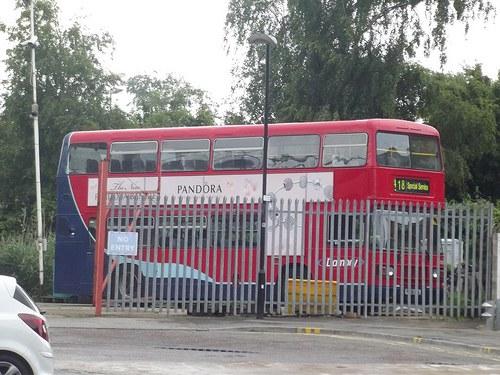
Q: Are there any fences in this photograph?
A: Yes, there is a fence.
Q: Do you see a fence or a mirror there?
A: Yes, there is a fence.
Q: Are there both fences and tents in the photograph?
A: No, there is a fence but no tents.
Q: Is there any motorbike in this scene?
A: No, there are no motorcycles.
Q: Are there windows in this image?
A: Yes, there is a window.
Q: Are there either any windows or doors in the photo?
A: Yes, there is a window.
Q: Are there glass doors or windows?
A: Yes, there is a glass window.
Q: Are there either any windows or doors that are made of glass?
A: Yes, the window is made of glass.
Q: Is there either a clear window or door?
A: Yes, there is a clear window.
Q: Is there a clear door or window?
A: Yes, there is a clear window.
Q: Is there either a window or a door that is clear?
A: Yes, the window is clear.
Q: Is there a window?
A: Yes, there is a window.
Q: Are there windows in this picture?
A: Yes, there is a window.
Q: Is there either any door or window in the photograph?
A: Yes, there is a window.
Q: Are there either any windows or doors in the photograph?
A: Yes, there is a window.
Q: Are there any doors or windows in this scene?
A: Yes, there is a window.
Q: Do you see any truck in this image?
A: No, there are no trucks.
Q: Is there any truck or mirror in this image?
A: No, there are no trucks or mirrors.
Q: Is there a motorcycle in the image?
A: No, there are no motorcycles.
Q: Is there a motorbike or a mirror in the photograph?
A: No, there are no motorcycles or mirrors.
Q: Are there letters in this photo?
A: Yes, there are letters.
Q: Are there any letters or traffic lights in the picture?
A: Yes, there are letters.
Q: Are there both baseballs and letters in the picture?
A: No, there are letters but no baseballs.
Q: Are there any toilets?
A: No, there are no toilets.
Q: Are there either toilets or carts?
A: No, there are no toilets or carts.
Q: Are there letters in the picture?
A: Yes, there are letters.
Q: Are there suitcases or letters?
A: Yes, there are letters.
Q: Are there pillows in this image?
A: No, there are no pillows.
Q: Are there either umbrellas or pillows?
A: No, there are no pillows or umbrellas.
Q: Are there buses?
A: Yes, there is a bus.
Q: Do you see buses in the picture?
A: Yes, there is a bus.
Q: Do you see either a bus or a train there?
A: Yes, there is a bus.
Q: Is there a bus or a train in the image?
A: Yes, there is a bus.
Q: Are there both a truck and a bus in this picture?
A: No, there is a bus but no trucks.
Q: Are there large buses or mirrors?
A: Yes, there is a large bus.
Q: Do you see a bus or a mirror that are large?
A: Yes, the bus is large.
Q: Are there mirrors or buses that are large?
A: Yes, the bus is large.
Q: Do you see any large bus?
A: Yes, there is a large bus.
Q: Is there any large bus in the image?
A: Yes, there is a large bus.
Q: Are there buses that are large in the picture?
A: Yes, there is a large bus.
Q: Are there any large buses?
A: Yes, there is a large bus.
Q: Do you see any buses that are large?
A: Yes, there is a bus that is large.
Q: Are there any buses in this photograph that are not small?
A: Yes, there is a large bus.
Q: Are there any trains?
A: No, there are no trains.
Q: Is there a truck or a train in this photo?
A: No, there are no trains or trucks.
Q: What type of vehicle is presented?
A: The vehicle is a bus.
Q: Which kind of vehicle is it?
A: The vehicle is a bus.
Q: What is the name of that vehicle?
A: This is a bus.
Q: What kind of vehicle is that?
A: This is a bus.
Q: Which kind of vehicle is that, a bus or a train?
A: This is a bus.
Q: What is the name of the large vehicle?
A: The vehicle is a bus.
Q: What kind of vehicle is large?
A: The vehicle is a bus.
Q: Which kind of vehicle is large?
A: The vehicle is a bus.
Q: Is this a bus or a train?
A: This is a bus.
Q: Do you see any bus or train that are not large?
A: No, there is a bus but it is large.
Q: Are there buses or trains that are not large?
A: No, there is a bus but it is large.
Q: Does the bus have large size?
A: Yes, the bus is large.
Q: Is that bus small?
A: No, the bus is large.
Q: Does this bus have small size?
A: No, the bus is large.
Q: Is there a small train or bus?
A: No, there is a bus but it is large.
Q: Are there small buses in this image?
A: No, there is a bus but it is large.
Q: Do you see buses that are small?
A: No, there is a bus but it is large.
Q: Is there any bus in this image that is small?
A: No, there is a bus but it is large.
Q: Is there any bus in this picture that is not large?
A: No, there is a bus but it is large.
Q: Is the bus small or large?
A: The bus is large.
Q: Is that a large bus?
A: Yes, that is a large bus.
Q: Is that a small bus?
A: No, that is a large bus.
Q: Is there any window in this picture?
A: Yes, there is a window.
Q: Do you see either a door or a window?
A: Yes, there is a window.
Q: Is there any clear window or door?
A: Yes, there is a clear window.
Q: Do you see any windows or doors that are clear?
A: Yes, the window is clear.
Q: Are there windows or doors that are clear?
A: Yes, the window is clear.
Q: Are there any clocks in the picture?
A: No, there are no clocks.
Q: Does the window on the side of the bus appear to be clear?
A: Yes, the window is clear.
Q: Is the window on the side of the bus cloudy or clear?
A: The window is clear.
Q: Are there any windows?
A: Yes, there is a window.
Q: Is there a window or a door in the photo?
A: Yes, there is a window.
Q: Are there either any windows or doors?
A: Yes, there is a window.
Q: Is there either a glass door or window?
A: Yes, there is a glass window.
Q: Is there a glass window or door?
A: Yes, there is a glass window.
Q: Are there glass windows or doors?
A: Yes, there is a glass window.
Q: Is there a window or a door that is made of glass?
A: Yes, the window is made of glass.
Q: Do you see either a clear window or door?
A: Yes, there is a clear window.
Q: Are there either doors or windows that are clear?
A: Yes, the window is clear.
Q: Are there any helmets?
A: No, there are no helmets.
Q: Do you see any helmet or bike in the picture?
A: No, there are no helmets or bikes.